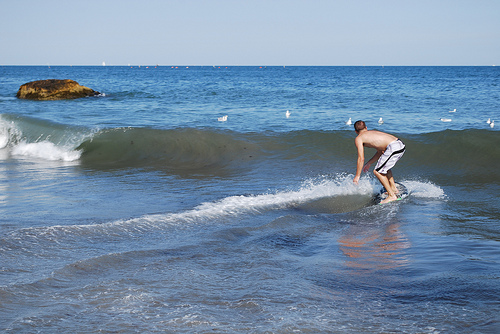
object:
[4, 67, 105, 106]
rock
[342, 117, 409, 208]
surfer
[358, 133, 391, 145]
skin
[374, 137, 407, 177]
shorts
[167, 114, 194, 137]
waves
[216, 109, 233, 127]
seafull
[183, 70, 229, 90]
ocean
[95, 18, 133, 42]
sky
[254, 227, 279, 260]
water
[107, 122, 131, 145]
wave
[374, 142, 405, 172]
trunks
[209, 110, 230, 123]
bird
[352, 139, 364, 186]
arm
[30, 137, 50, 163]
foam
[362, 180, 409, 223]
surfboard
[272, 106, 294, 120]
birds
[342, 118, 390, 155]
forward